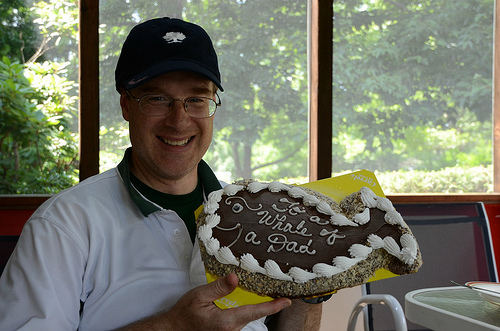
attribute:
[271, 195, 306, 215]
word — white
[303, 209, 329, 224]
word — white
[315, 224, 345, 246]
word — white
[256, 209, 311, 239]
word — white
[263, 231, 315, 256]
word — white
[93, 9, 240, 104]
hat — black, baseball hat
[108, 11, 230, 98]
hat — black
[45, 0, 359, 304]
man — smiling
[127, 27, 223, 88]
hat — black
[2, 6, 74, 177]
bushes — green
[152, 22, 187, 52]
logo — tree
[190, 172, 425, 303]
cake — whale-shaped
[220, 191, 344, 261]
decorations — white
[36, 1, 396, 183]
tree — green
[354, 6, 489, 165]
tree — green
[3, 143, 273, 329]
shirt — white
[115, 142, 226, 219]
collar — green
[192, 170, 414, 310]
plate — yellow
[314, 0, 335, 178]
frame — wood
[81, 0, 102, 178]
frame — wood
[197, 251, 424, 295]
almonds — crushed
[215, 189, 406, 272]
frosting — chocolate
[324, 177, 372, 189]
board — yellow